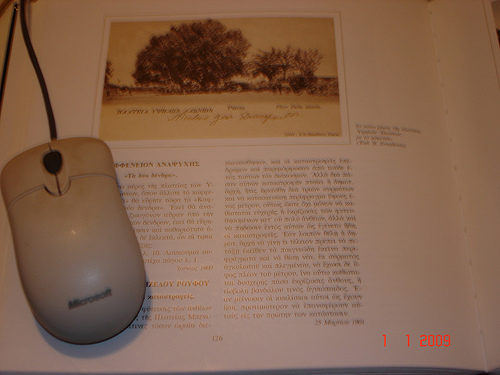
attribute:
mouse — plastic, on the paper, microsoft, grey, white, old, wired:
[1, 137, 147, 346]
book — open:
[0, 1, 499, 374]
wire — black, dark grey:
[18, 0, 59, 142]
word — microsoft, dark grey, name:
[68, 288, 112, 310]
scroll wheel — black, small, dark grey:
[43, 151, 62, 174]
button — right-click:
[49, 137, 118, 196]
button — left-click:
[1, 143, 60, 208]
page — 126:
[2, 0, 487, 374]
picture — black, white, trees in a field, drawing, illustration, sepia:
[97, 17, 342, 142]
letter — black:
[177, 281, 182, 288]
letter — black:
[155, 162, 161, 168]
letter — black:
[204, 280, 209, 286]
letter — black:
[245, 188, 249, 193]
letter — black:
[323, 320, 330, 326]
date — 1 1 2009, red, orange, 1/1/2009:
[383, 333, 451, 347]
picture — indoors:
[0, 1, 500, 374]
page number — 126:
[211, 335, 223, 342]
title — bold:
[114, 162, 200, 169]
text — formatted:
[111, 158, 366, 329]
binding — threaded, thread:
[426, 1, 490, 373]